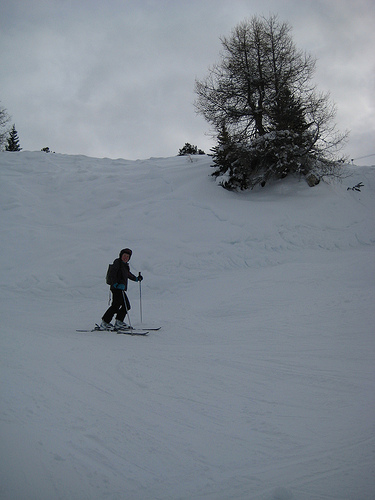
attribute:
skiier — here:
[99, 249, 143, 330]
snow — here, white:
[0, 150, 375, 500]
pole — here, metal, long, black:
[137, 271, 144, 328]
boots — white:
[99, 319, 117, 331]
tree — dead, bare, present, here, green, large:
[194, 14, 353, 190]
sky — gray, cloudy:
[0, 0, 373, 168]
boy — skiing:
[99, 248, 144, 333]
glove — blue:
[136, 274, 144, 283]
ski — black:
[73, 327, 160, 337]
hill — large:
[0, 149, 375, 500]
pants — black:
[102, 285, 131, 323]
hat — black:
[119, 248, 133, 263]